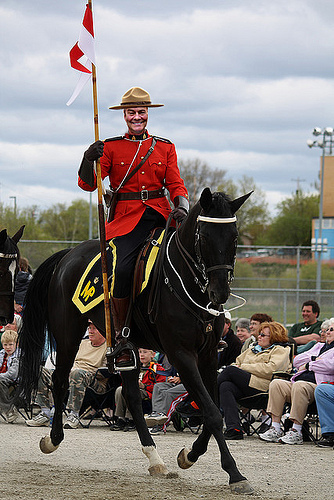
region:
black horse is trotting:
[46, 222, 256, 358]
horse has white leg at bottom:
[123, 422, 172, 485]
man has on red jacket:
[87, 131, 190, 225]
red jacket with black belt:
[109, 173, 168, 221]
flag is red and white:
[54, 9, 112, 103]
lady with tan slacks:
[263, 373, 319, 423]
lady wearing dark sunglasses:
[255, 326, 277, 352]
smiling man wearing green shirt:
[298, 307, 322, 334]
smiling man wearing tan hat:
[95, 76, 183, 124]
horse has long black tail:
[14, 249, 47, 384]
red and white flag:
[58, 5, 102, 74]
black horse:
[189, 186, 243, 368]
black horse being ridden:
[51, 195, 233, 484]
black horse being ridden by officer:
[35, 192, 224, 484]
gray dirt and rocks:
[257, 449, 326, 495]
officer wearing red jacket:
[107, 139, 175, 216]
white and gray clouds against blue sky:
[9, 5, 64, 202]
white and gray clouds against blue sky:
[99, 5, 324, 90]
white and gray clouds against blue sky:
[173, 41, 304, 149]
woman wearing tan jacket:
[250, 342, 280, 373]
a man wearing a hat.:
[103, 82, 181, 144]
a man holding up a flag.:
[63, 0, 179, 354]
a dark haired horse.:
[13, 188, 269, 491]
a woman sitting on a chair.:
[210, 309, 295, 440]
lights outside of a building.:
[304, 125, 332, 304]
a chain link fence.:
[0, 232, 331, 293]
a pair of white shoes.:
[139, 406, 176, 436]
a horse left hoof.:
[176, 442, 210, 467]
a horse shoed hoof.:
[169, 440, 208, 468]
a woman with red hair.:
[247, 311, 296, 364]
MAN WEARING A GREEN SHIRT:
[284, 299, 325, 340]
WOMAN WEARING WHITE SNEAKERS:
[259, 319, 332, 449]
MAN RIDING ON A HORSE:
[12, 0, 265, 498]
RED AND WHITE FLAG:
[63, 1, 101, 112]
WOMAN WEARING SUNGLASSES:
[253, 322, 290, 351]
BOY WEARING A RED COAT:
[135, 347, 167, 402]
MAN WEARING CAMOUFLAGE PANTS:
[26, 320, 106, 433]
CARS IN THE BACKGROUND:
[241, 245, 291, 262]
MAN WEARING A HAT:
[105, 85, 166, 141]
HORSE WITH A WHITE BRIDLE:
[166, 217, 252, 319]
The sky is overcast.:
[148, 33, 318, 143]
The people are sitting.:
[18, 278, 319, 445]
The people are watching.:
[16, 279, 328, 443]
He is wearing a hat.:
[107, 78, 198, 144]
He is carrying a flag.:
[48, 9, 127, 133]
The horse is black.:
[50, 184, 263, 497]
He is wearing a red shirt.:
[75, 129, 188, 247]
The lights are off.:
[286, 121, 332, 237]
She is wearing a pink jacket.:
[258, 326, 333, 455]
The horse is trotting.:
[23, 201, 287, 496]